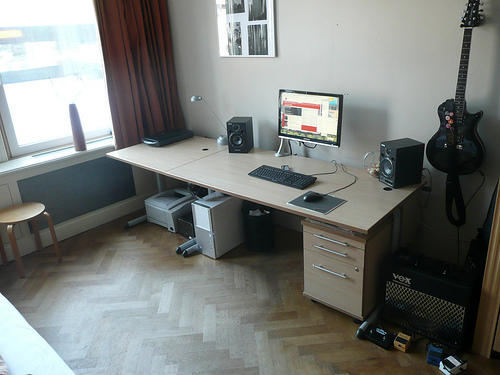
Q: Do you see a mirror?
A: No, there are no mirrors.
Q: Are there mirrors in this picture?
A: No, there are no mirrors.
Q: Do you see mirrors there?
A: No, there are no mirrors.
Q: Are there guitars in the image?
A: Yes, there is a guitar.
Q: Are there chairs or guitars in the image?
A: Yes, there is a guitar.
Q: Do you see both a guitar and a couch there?
A: No, there is a guitar but no couches.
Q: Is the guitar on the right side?
A: Yes, the guitar is on the right of the image.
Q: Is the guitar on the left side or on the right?
A: The guitar is on the right of the image.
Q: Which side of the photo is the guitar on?
A: The guitar is on the right of the image.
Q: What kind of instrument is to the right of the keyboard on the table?
A: The instrument is a guitar.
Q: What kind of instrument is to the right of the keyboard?
A: The instrument is a guitar.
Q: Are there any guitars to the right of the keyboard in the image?
A: Yes, there is a guitar to the right of the keyboard.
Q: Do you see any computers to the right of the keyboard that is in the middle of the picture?
A: No, there is a guitar to the right of the keyboard.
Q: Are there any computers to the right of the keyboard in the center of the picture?
A: No, there is a guitar to the right of the keyboard.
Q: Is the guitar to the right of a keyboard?
A: Yes, the guitar is to the right of a keyboard.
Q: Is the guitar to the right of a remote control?
A: No, the guitar is to the right of a keyboard.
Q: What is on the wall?
A: The guitar is on the wall.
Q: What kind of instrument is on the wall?
A: The instrument is a guitar.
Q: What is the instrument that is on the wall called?
A: The instrument is a guitar.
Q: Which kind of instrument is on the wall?
A: The instrument is a guitar.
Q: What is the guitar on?
A: The guitar is on the wall.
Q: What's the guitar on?
A: The guitar is on the wall.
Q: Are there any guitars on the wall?
A: Yes, there is a guitar on the wall.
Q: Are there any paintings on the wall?
A: No, there is a guitar on the wall.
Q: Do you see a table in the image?
A: Yes, there is a table.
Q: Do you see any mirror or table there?
A: Yes, there is a table.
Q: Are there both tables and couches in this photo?
A: No, there is a table but no couches.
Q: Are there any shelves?
A: No, there are no shelves.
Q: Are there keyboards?
A: Yes, there is a keyboard.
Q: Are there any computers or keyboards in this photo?
A: Yes, there is a keyboard.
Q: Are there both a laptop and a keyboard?
A: No, there is a keyboard but no laptops.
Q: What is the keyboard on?
A: The keyboard is on the table.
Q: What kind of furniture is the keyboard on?
A: The keyboard is on the table.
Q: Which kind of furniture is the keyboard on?
A: The keyboard is on the table.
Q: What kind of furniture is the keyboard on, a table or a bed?
A: The keyboard is on a table.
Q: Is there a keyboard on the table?
A: Yes, there is a keyboard on the table.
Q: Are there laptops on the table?
A: No, there is a keyboard on the table.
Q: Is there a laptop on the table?
A: No, there is a keyboard on the table.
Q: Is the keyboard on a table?
A: Yes, the keyboard is on a table.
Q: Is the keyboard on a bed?
A: No, the keyboard is on a table.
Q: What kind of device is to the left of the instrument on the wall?
A: The device is a keyboard.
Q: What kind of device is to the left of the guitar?
A: The device is a keyboard.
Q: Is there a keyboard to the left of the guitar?
A: Yes, there is a keyboard to the left of the guitar.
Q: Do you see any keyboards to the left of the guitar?
A: Yes, there is a keyboard to the left of the guitar.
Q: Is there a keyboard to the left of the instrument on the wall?
A: Yes, there is a keyboard to the left of the guitar.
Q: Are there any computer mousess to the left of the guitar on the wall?
A: No, there is a keyboard to the left of the guitar.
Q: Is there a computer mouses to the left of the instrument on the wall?
A: No, there is a keyboard to the left of the guitar.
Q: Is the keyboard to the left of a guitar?
A: Yes, the keyboard is to the left of a guitar.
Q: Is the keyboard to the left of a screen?
A: No, the keyboard is to the left of a guitar.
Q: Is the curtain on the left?
A: Yes, the curtain is on the left of the image.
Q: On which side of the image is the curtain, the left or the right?
A: The curtain is on the left of the image.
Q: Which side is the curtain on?
A: The curtain is on the left of the image.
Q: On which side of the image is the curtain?
A: The curtain is on the left of the image.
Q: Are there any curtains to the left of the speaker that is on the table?
A: Yes, there is a curtain to the left of the speaker.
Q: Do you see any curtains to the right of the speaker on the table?
A: No, the curtain is to the left of the speaker.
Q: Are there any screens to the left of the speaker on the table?
A: No, there is a curtain to the left of the speaker.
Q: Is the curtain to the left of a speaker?
A: Yes, the curtain is to the left of a speaker.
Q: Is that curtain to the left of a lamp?
A: No, the curtain is to the left of a speaker.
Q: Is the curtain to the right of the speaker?
A: No, the curtain is to the left of the speaker.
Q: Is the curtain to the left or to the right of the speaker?
A: The curtain is to the left of the speaker.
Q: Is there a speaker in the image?
A: Yes, there is a speaker.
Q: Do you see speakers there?
A: Yes, there is a speaker.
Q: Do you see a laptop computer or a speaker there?
A: Yes, there is a speaker.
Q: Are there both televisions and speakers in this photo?
A: No, there is a speaker but no televisions.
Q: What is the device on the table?
A: The device is a speaker.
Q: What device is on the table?
A: The device is a speaker.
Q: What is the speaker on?
A: The speaker is on the table.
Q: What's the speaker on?
A: The speaker is on the table.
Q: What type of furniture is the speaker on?
A: The speaker is on the table.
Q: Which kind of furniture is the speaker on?
A: The speaker is on the table.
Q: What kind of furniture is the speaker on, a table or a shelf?
A: The speaker is on a table.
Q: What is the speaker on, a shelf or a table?
A: The speaker is on a table.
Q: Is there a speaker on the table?
A: Yes, there is a speaker on the table.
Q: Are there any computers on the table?
A: No, there is a speaker on the table.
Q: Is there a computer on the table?
A: No, there is a speaker on the table.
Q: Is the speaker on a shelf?
A: No, the speaker is on a table.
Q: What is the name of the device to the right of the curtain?
A: The device is a speaker.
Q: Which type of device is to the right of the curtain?
A: The device is a speaker.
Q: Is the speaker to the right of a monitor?
A: No, the speaker is to the right of a curtain.